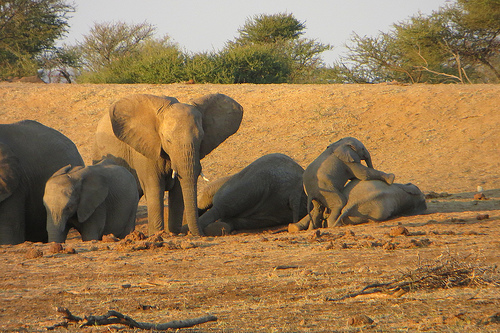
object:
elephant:
[181, 152, 311, 238]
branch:
[44, 308, 221, 329]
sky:
[33, 2, 478, 89]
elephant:
[286, 175, 425, 232]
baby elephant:
[43, 164, 139, 244]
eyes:
[158, 127, 170, 139]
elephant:
[0, 119, 83, 246]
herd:
[1, 90, 430, 247]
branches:
[325, 255, 498, 303]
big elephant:
[93, 92, 243, 236]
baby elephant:
[287, 136, 395, 234]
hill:
[0, 81, 500, 232]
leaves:
[0, 0, 500, 84]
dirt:
[0, 78, 497, 333]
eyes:
[188, 123, 206, 132]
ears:
[108, 93, 243, 162]